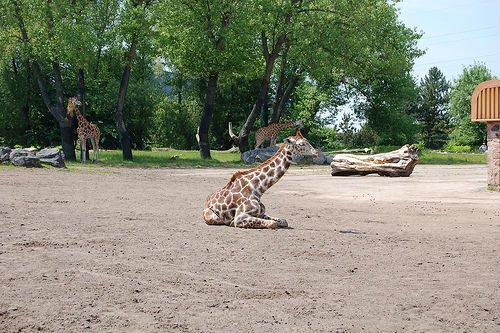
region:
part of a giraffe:
[268, 200, 278, 224]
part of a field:
[181, 140, 186, 147]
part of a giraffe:
[219, 173, 228, 197]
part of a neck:
[271, 163, 278, 173]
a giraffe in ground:
[153, 76, 305, 223]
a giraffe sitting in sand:
[181, 104, 378, 282]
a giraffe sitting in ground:
[171, 118, 379, 260]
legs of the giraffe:
[246, 203, 298, 241]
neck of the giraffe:
[251, 148, 301, 199]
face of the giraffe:
[275, 130, 332, 172]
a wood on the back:
[323, 139, 443, 200]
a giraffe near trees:
[51, 100, 149, 189]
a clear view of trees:
[33, 13, 432, 110]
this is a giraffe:
[180, 138, 384, 280]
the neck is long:
[173, 110, 344, 233]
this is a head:
[252, 86, 328, 204]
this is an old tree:
[230, 54, 277, 99]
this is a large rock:
[12, 153, 60, 160]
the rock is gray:
[54, 145, 82, 234]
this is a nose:
[314, 131, 321, 173]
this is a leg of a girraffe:
[236, 213, 282, 231]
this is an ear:
[287, 136, 295, 145]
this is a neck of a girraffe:
[255, 157, 288, 186]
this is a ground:
[69, 231, 416, 306]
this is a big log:
[339, 142, 422, 179]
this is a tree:
[177, 13, 236, 155]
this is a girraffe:
[57, 92, 103, 164]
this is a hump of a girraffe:
[222, 172, 257, 186]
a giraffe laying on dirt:
[205, 132, 316, 229]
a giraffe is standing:
[65, 96, 99, 165]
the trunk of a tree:
[120, 28, 139, 161]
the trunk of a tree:
[195, 68, 217, 158]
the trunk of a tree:
[33, 58, 85, 161]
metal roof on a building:
[468, 76, 499, 119]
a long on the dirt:
[329, 141, 420, 178]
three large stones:
[1, 146, 65, 172]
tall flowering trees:
[0, 0, 426, 161]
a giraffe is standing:
[256, 117, 304, 145]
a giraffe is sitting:
[203, 134, 315, 234]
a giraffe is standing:
[69, 101, 105, 162]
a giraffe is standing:
[252, 118, 305, 153]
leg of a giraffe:
[232, 205, 276, 226]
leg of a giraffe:
[259, 210, 289, 227]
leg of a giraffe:
[252, 137, 260, 147]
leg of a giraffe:
[268, 134, 275, 145]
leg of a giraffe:
[80, 135, 87, 164]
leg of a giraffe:
[94, 134, 102, 156]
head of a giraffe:
[70, 98, 80, 108]